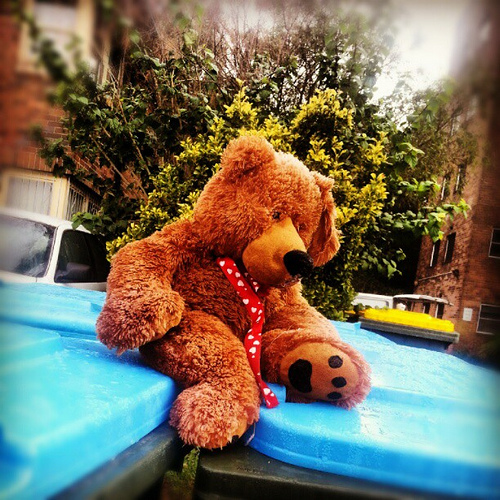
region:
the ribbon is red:
[204, 247, 276, 397]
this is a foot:
[276, 348, 331, 399]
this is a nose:
[258, 263, 294, 276]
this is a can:
[15, 384, 59, 410]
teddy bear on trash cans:
[21, 52, 492, 488]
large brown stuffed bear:
[78, 130, 418, 467]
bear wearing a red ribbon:
[88, 133, 400, 453]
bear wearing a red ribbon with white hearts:
[87, 137, 421, 474]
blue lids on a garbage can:
[242, 294, 499, 496]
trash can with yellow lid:
[355, 272, 460, 359]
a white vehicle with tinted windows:
[3, 202, 148, 322]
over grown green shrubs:
[42, 17, 464, 319]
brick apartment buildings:
[364, 13, 496, 365]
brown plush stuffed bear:
[99, 135, 365, 451]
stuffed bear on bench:
[99, 135, 369, 446]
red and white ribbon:
[218, 254, 281, 411]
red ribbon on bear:
[220, 254, 279, 414]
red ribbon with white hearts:
[213, 258, 281, 412]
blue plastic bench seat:
[244, 316, 498, 499]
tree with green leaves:
[108, 92, 463, 324]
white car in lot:
[1, 205, 109, 292]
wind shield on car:
[0, 217, 58, 279]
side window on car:
[58, 232, 109, 282]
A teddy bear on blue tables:
[90, 105, 382, 459]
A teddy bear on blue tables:
[88, 123, 380, 457]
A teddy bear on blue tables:
[87, 126, 372, 456]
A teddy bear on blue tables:
[97, 119, 395, 454]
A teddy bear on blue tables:
[85, 118, 377, 455]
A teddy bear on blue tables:
[84, 125, 382, 455]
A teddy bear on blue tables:
[91, 116, 376, 458]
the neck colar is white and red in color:
[222, 203, 289, 467]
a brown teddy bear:
[112, 133, 379, 464]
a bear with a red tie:
[186, 148, 310, 415]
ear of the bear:
[227, 141, 264, 171]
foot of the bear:
[156, 374, 263, 434]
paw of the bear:
[102, 289, 187, 342]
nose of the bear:
[282, 243, 309, 270]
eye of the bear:
[262, 202, 286, 228]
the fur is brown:
[170, 341, 229, 371]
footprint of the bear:
[289, 358, 317, 396]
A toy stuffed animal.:
[100, 105, 393, 466]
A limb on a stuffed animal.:
[96, 226, 188, 348]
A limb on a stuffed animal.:
[149, 307, 254, 441]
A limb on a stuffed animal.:
[246, 318, 398, 413]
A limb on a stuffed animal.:
[261, 291, 353, 361]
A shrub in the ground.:
[86, 127, 172, 269]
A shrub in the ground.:
[285, 81, 386, 348]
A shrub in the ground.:
[41, 21, 321, 198]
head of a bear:
[184, 138, 361, 291]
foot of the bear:
[283, 323, 373, 415]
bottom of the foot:
[273, 345, 365, 405]